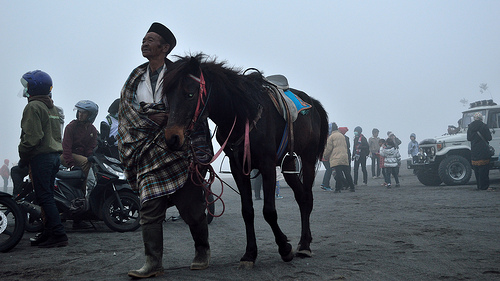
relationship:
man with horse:
[114, 22, 232, 279] [157, 50, 332, 268]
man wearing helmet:
[14, 67, 77, 250] [21, 69, 53, 96]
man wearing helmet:
[59, 96, 106, 170] [74, 99, 100, 123]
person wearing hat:
[468, 107, 497, 188] [474, 110, 482, 121]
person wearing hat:
[324, 117, 355, 197] [331, 120, 341, 132]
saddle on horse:
[261, 72, 298, 120] [157, 50, 332, 268]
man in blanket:
[114, 22, 232, 279] [120, 57, 205, 207]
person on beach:
[378, 138, 404, 188] [6, 150, 500, 256]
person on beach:
[324, 117, 355, 197] [6, 150, 500, 256]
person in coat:
[378, 138, 404, 188] [380, 144, 400, 171]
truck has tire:
[406, 89, 500, 191] [437, 151, 475, 183]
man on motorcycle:
[59, 96, 106, 170] [18, 154, 151, 235]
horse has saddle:
[157, 50, 332, 268] [261, 72, 298, 120]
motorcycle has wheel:
[18, 154, 151, 235] [100, 188, 146, 233]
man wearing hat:
[114, 22, 232, 279] [147, 22, 179, 49]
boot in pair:
[128, 222, 168, 278] [130, 211, 214, 278]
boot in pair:
[185, 210, 213, 272] [130, 211, 214, 278]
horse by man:
[157, 50, 332, 268] [114, 22, 232, 279]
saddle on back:
[261, 72, 298, 120] [252, 80, 316, 127]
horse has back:
[157, 50, 332, 268] [252, 80, 316, 127]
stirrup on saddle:
[277, 150, 305, 175] [261, 72, 298, 120]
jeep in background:
[406, 89, 500, 191] [12, 0, 499, 236]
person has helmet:
[14, 67, 77, 250] [21, 69, 53, 96]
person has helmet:
[59, 96, 106, 170] [74, 99, 100, 123]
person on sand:
[352, 124, 369, 187] [6, 150, 500, 256]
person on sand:
[324, 117, 355, 197] [6, 150, 500, 256]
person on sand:
[468, 107, 497, 188] [7, 162, 500, 273]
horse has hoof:
[157, 50, 332, 268] [279, 249, 295, 261]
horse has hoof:
[157, 50, 332, 268] [243, 251, 259, 264]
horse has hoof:
[157, 50, 332, 268] [297, 242, 313, 255]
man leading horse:
[114, 22, 232, 279] [157, 50, 332, 268]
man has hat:
[114, 22, 232, 279] [147, 22, 179, 49]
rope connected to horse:
[183, 135, 227, 222] [157, 50, 332, 268]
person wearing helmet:
[14, 67, 77, 250] [21, 69, 53, 96]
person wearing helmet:
[59, 96, 106, 170] [74, 99, 100, 123]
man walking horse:
[114, 22, 232, 279] [157, 50, 332, 268]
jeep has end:
[405, 93, 500, 199] [407, 126, 479, 185]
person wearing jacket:
[378, 138, 404, 188] [380, 144, 400, 171]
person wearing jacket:
[324, 117, 355, 197] [324, 130, 354, 171]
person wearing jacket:
[468, 107, 497, 188] [466, 120, 493, 163]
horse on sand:
[157, 50, 332, 268] [7, 162, 500, 273]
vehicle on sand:
[406, 89, 500, 191] [7, 162, 500, 273]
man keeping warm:
[114, 22, 232, 279] [113, 51, 207, 207]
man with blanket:
[114, 22, 232, 279] [120, 57, 205, 207]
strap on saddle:
[280, 155, 305, 172] [261, 72, 298, 120]